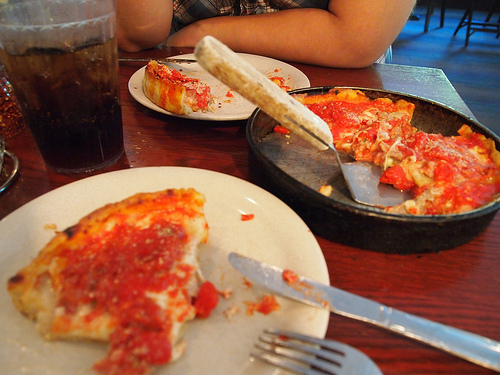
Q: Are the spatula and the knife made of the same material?
A: Yes, both the spatula and the knife are made of metal.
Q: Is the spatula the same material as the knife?
A: Yes, both the spatula and the knife are made of metal.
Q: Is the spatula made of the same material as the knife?
A: Yes, both the spatula and the knife are made of metal.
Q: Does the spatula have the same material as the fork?
A: Yes, both the spatula and the fork are made of metal.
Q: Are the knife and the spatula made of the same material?
A: Yes, both the knife and the spatula are made of metal.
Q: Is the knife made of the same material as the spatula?
A: Yes, both the knife and the spatula are made of metal.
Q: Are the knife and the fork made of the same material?
A: Yes, both the knife and the fork are made of metal.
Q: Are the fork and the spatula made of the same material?
A: Yes, both the fork and the spatula are made of metal.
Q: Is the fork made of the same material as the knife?
A: Yes, both the fork and the knife are made of metal.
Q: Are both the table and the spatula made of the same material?
A: No, the table is made of wood and the spatula is made of metal.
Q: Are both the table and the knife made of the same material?
A: No, the table is made of wood and the knife is made of metal.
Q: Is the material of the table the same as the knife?
A: No, the table is made of wood and the knife is made of metal.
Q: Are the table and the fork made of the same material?
A: No, the table is made of wood and the fork is made of metal.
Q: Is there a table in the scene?
A: Yes, there is a table.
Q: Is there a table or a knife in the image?
A: Yes, there is a table.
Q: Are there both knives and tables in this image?
A: Yes, there are both a table and a knife.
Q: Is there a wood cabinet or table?
A: Yes, there is a wood table.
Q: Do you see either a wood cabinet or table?
A: Yes, there is a wood table.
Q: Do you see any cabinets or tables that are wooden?
A: Yes, the table is wooden.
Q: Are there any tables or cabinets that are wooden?
A: Yes, the table is wooden.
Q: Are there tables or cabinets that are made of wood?
A: Yes, the table is made of wood.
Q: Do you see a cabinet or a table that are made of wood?
A: Yes, the table is made of wood.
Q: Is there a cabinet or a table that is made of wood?
A: Yes, the table is made of wood.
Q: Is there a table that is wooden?
A: Yes, there is a wood table.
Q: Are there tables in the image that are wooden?
A: Yes, there is a table that is wooden.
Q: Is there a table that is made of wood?
A: Yes, there is a table that is made of wood.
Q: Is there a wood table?
A: Yes, there is a table that is made of wood.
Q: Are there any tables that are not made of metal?
A: Yes, there is a table that is made of wood.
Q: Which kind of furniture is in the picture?
A: The furniture is a table.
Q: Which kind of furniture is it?
A: The piece of furniture is a table.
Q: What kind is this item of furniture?
A: That is a table.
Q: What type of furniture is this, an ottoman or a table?
A: That is a table.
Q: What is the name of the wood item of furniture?
A: The piece of furniture is a table.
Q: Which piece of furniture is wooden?
A: The piece of furniture is a table.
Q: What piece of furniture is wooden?
A: The piece of furniture is a table.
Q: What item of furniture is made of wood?
A: The piece of furniture is a table.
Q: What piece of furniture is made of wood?
A: The piece of furniture is a table.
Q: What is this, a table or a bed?
A: This is a table.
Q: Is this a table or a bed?
A: This is a table.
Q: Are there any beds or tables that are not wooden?
A: No, there is a table but it is wooden.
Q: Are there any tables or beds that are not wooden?
A: No, there is a table but it is wooden.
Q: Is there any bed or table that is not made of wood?
A: No, there is a table but it is made of wood.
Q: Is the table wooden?
A: Yes, the table is wooden.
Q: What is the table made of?
A: The table is made of wood.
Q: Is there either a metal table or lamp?
A: No, there is a table but it is wooden.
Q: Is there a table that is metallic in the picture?
A: No, there is a table but it is wooden.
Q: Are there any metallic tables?
A: No, there is a table but it is wooden.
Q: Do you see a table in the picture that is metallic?
A: No, there is a table but it is wooden.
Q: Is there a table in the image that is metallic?
A: No, there is a table but it is wooden.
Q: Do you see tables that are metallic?
A: No, there is a table but it is wooden.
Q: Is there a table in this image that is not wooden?
A: No, there is a table but it is wooden.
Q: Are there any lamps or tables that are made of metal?
A: No, there is a table but it is made of wood.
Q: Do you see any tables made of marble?
A: No, there is a table but it is made of wood.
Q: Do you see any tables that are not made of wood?
A: No, there is a table but it is made of wood.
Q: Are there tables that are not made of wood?
A: No, there is a table but it is made of wood.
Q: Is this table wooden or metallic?
A: The table is wooden.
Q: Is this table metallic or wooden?
A: The table is wooden.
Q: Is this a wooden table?
A: Yes, this is a wooden table.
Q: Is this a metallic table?
A: No, this is a wooden table.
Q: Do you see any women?
A: No, there are no women.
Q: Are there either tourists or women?
A: No, there are no women or tourists.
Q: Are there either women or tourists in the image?
A: No, there are no women or tourists.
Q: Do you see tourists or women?
A: No, there are no women or tourists.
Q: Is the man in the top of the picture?
A: Yes, the man is in the top of the image.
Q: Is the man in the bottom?
A: No, the man is in the top of the image.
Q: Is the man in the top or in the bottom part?
A: The man is in the top of the image.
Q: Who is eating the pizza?
A: The man is eating the pizza.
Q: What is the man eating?
A: The man is eating a pizza.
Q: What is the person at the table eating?
A: The man is eating a pizza.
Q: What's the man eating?
A: The man is eating a pizza.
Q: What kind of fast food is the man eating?
A: The man is eating a pizza.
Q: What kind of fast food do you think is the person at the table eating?
A: The man is eating a pizza.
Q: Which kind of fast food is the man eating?
A: The man is eating a pizza.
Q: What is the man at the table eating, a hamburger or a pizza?
A: The man is eating a pizza.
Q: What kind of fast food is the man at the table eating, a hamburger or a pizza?
A: The man is eating a pizza.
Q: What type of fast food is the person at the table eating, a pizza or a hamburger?
A: The man is eating a pizza.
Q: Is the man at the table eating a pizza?
A: Yes, the man is eating a pizza.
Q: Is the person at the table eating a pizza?
A: Yes, the man is eating a pizza.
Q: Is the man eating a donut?
A: No, the man is eating a pizza.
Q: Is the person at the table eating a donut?
A: No, the man is eating a pizza.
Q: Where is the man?
A: The man is at the table.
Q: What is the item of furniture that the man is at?
A: The piece of furniture is a table.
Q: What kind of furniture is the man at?
A: The man is at the table.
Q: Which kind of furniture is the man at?
A: The man is at the table.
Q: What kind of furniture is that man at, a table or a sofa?
A: The man is at a table.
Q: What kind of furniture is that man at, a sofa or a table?
A: The man is at a table.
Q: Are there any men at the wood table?
A: Yes, there is a man at the table.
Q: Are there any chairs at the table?
A: No, there is a man at the table.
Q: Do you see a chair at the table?
A: No, there is a man at the table.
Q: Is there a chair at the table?
A: No, there is a man at the table.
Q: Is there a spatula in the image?
A: Yes, there is a spatula.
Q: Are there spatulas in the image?
A: Yes, there is a spatula.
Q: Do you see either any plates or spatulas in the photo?
A: Yes, there is a spatula.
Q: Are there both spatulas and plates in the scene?
A: Yes, there are both a spatula and a plate.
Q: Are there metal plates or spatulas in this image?
A: Yes, there is a metal spatula.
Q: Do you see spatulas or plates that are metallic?
A: Yes, the spatula is metallic.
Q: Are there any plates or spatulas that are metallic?
A: Yes, the spatula is metallic.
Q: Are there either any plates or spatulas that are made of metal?
A: Yes, the spatula is made of metal.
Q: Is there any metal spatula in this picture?
A: Yes, there is a metal spatula.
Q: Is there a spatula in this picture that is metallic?
A: Yes, there is a spatula that is metallic.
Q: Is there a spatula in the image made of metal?
A: Yes, there is a spatula that is made of metal.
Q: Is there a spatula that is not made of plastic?
A: Yes, there is a spatula that is made of metal.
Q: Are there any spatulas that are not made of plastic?
A: Yes, there is a spatula that is made of metal.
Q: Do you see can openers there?
A: No, there are no can openers.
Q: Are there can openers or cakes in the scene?
A: No, there are no can openers or cakes.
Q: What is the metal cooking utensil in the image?
A: The cooking utensil is a spatula.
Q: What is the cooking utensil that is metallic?
A: The cooking utensil is a spatula.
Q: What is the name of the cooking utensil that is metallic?
A: The cooking utensil is a spatula.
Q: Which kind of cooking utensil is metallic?
A: The cooking utensil is a spatula.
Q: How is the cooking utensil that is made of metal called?
A: The cooking utensil is a spatula.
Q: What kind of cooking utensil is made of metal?
A: The cooking utensil is a spatula.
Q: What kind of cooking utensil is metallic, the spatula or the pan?
A: The spatula is metallic.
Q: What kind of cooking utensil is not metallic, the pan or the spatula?
A: The pan is not metallic.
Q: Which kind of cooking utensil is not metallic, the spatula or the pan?
A: The pan is not metallic.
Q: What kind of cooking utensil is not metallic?
A: The cooking utensil is a pan.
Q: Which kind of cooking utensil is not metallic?
A: The cooking utensil is a pan.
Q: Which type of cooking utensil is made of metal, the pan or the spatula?
A: The spatula is made of metal.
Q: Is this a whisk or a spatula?
A: This is a spatula.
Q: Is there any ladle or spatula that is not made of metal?
A: No, there is a spatula but it is made of metal.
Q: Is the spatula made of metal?
A: Yes, the spatula is made of metal.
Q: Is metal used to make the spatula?
A: Yes, the spatula is made of metal.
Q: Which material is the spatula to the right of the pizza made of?
A: The spatula is made of metal.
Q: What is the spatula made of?
A: The spatula is made of metal.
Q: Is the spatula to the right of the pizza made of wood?
A: No, the spatula is made of metal.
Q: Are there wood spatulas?
A: No, there is a spatula but it is made of metal.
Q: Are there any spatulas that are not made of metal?
A: No, there is a spatula but it is made of metal.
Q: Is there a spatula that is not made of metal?
A: No, there is a spatula but it is made of metal.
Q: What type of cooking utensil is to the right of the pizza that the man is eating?
A: The cooking utensil is a spatula.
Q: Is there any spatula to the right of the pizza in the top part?
A: Yes, there is a spatula to the right of the pizza.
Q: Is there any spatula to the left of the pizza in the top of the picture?
A: No, the spatula is to the right of the pizza.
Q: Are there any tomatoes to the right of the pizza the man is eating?
A: No, there is a spatula to the right of the pizza.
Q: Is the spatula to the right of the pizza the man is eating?
A: Yes, the spatula is to the right of the pizza.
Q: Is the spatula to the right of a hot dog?
A: No, the spatula is to the right of the pizza.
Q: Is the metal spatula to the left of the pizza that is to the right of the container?
A: No, the spatula is to the right of the pizza.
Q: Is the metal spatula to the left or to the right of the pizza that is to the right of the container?
A: The spatula is to the right of the pizza.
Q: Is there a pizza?
A: Yes, there is a pizza.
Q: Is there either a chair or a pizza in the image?
A: Yes, there is a pizza.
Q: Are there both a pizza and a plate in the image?
A: Yes, there are both a pizza and a plate.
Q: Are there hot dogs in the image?
A: No, there are no hot dogs.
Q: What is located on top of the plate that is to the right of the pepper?
A: The pizza is on top of the plate.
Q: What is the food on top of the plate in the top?
A: The food is a pizza.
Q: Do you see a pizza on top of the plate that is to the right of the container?
A: Yes, there is a pizza on top of the plate.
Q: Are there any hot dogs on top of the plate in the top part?
A: No, there is a pizza on top of the plate.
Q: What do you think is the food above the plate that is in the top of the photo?
A: The food is a pizza.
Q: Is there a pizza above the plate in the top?
A: Yes, there is a pizza above the plate.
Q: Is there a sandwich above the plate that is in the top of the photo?
A: No, there is a pizza above the plate.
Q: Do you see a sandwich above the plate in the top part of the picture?
A: No, there is a pizza above the plate.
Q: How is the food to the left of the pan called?
A: The food is a pizza.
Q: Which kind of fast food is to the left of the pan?
A: The food is a pizza.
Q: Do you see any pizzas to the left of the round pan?
A: Yes, there is a pizza to the left of the pan.